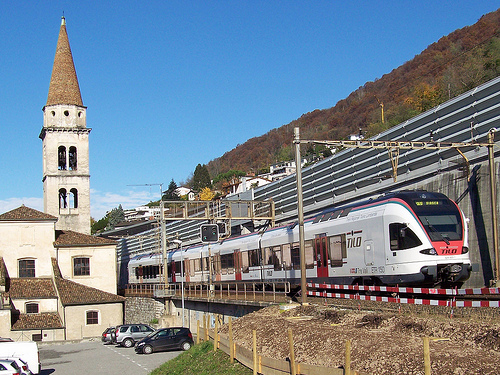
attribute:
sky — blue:
[2, 2, 495, 219]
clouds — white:
[2, 185, 164, 222]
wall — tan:
[20, 204, 120, 348]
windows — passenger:
[148, 233, 362, 277]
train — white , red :
[122, 181, 479, 289]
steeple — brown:
[46, 16, 93, 110]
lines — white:
[101, 113, 490, 263]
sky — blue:
[4, 3, 444, 214]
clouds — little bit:
[90, 185, 158, 201]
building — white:
[1, 8, 141, 361]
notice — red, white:
[305, 280, 497, 308]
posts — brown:
[189, 315, 439, 373]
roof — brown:
[9, 199, 56, 225]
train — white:
[127, 188, 472, 286]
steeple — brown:
[41, 15, 87, 109]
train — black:
[179, 157, 496, 282]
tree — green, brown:
[477, 37, 497, 81]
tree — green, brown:
[439, 47, 471, 99]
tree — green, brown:
[391, 90, 410, 127]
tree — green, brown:
[360, 117, 383, 142]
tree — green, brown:
[272, 137, 314, 168]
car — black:
[134, 317, 194, 357]